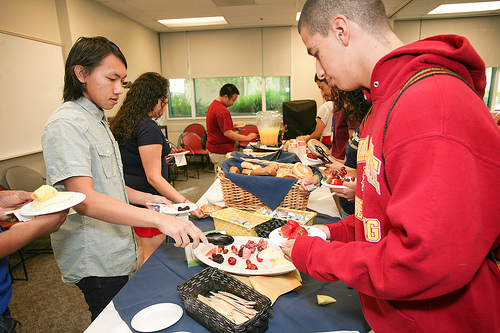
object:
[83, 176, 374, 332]
tablecloth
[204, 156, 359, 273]
food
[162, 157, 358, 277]
buffett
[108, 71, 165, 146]
hair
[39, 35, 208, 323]
boy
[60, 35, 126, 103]
long hair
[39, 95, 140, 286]
green shirt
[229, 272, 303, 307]
cloth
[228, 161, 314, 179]
bread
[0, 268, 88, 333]
ground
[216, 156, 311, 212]
basket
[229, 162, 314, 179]
bagels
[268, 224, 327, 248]
plate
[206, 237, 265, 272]
strawberries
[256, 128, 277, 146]
fruit juice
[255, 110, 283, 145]
container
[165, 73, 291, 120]
window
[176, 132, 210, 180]
red chair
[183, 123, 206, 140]
red chair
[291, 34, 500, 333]
hoodie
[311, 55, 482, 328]
sweatshirt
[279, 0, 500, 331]
boy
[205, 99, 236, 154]
shirt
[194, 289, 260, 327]
spoons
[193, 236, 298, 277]
plate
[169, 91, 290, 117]
greens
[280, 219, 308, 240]
strawberries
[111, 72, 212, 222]
person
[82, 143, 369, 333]
table